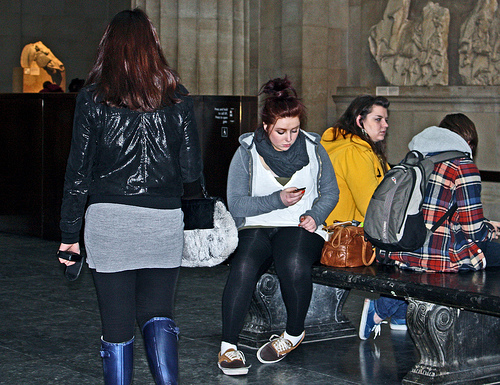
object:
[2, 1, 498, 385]
museum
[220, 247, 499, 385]
bech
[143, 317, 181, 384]
shoe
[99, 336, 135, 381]
shoe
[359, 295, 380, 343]
shoe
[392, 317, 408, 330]
shoe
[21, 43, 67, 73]
statue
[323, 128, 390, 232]
sweater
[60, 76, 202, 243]
jacket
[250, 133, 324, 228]
shirt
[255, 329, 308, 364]
sneakers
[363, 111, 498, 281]
girl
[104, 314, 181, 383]
boots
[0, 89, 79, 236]
desk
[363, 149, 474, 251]
backpack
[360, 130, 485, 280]
person's back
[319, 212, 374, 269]
brown bag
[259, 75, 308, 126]
brown hair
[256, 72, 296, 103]
bun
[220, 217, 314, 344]
pants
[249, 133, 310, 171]
scarf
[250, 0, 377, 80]
wall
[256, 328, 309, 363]
shoe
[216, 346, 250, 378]
shoe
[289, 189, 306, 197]
phone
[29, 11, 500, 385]
person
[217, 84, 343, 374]
girl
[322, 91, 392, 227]
girl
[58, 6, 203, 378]
girl